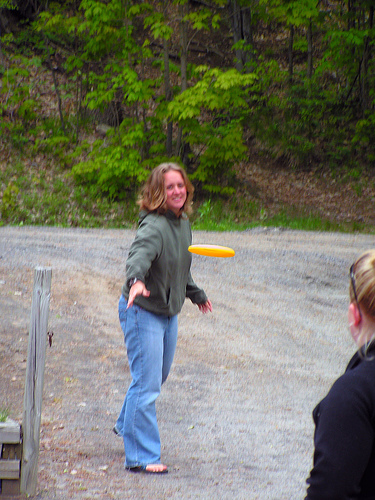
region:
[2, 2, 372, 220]
trees on side of hill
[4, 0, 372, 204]
green leaves on trees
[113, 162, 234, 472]
woman throwing frisbee in the air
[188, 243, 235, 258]
edge of yellow frisbee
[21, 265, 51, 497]
wood post with flat top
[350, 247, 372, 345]
glasses on woman's head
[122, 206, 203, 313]
hooded sweatshirt with pockets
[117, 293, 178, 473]
blue jeans on legs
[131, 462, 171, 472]
toes of woman in sandal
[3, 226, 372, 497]
unpaved surface of road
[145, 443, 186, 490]
this is a sandal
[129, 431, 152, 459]
this is a pair of jeans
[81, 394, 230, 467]
the jeans are blue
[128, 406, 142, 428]
this is a seam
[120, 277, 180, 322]
this is a hand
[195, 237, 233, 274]
this is a frisbee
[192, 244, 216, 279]
the frisbee is plastic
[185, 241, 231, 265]
the frisbee is plastic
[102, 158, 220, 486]
woman standing on gravel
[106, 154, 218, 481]
woman is throwing frisbee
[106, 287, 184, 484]
woman wearing blue jeans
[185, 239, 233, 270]
yellow frisbee in air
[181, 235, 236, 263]
woman throwing yellow frisbee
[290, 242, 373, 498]
woman waiting on frisbee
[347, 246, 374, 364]
womans hair is blonde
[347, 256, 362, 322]
sunglasses on womans head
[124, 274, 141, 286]
watch on womans right wrist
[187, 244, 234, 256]
the frisbee in mid air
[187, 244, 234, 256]
the flying frisbee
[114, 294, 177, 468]
the jeans on the woman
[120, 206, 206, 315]
the hoodie on the woman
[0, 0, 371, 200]
the trees behind the woman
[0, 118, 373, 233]
the green grass on the small hill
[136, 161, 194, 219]
the blond hair on the woman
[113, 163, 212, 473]
the woman behind the frisbee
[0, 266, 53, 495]
the wood object next to the woman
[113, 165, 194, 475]
this is a lady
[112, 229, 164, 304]
she is throwing the frisbee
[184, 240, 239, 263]
it is yellow in color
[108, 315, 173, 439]
these are the legs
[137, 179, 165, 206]
this is the hair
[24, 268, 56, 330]
this s a pole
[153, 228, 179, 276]
this is the jackeet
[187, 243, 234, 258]
a yellow frisbee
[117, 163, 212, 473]
woman playing frisbee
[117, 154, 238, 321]
A woman throwing a Frisbee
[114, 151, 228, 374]
a girl wearing a pair of blue jeans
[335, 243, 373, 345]
the head of a woman with blonde hair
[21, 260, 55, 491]
a Beige colored fence post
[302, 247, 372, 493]
A woman wearing a dark colored top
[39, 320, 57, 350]
a key hanging from a post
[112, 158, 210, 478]
a lady wearing sandals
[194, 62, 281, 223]
a Green bush in the background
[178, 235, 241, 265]
A yellow Frisbie in flight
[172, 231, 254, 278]
this is a yellow frisbee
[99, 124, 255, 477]
the woman threw the frisbee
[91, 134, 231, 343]
she is wearing a green hoodie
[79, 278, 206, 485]
she is wearing flare jeans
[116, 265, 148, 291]
this is a watch on her wrist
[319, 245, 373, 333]
she has sunglasses on her head